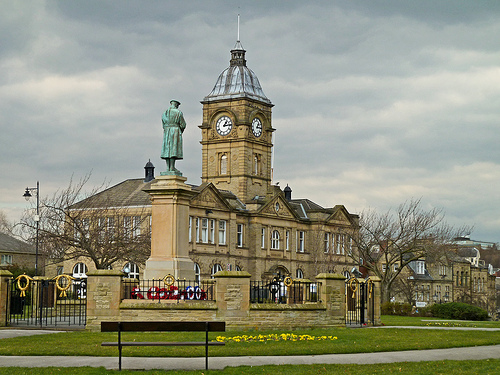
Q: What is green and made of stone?
A: Statue.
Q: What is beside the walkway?
A: Bench.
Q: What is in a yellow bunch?
A: Flowers.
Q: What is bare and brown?
A: Tree.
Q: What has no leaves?
A: Tree.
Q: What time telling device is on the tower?
A: Clock.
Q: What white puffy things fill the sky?
A: Clouds.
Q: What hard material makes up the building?
A: Stone.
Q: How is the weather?
A: Cloudy.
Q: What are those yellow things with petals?
A: Flowers.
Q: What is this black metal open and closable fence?
A: Gate.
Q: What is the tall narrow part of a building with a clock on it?
A: Clock tower.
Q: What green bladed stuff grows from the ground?
A: Grass.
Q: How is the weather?
A: Cloudy.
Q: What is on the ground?
A: Building.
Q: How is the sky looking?
A: Cloudy.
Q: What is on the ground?
A: Path.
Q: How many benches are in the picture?
A: One.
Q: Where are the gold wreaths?
A: On the gate.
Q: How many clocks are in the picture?
A: Two.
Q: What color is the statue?
A: Green.